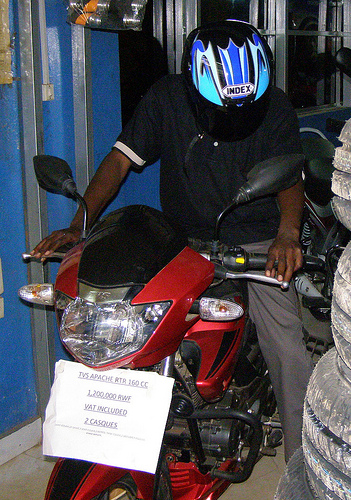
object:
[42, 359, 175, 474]
paper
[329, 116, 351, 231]
tires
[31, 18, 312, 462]
person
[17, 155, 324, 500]
motorcycle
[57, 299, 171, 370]
headlight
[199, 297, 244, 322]
lights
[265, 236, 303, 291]
hands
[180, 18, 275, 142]
helmet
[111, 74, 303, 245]
shirt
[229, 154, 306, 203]
mirrors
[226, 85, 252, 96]
index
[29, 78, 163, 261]
arm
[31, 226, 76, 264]
hand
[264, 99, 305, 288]
arm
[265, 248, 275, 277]
finger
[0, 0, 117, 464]
wall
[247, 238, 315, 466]
pants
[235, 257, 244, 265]
button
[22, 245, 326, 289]
handlebars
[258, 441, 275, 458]
foot hold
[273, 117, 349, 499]
dirt